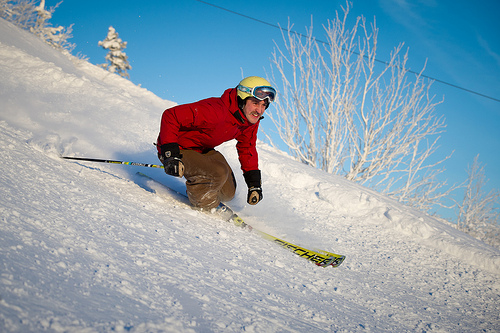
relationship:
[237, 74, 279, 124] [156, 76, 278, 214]
head of a man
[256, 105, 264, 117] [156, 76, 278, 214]
nose of a man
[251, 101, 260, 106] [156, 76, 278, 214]
eye of a man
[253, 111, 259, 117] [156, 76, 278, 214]
mouth of a man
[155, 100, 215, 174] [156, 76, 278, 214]
arm of a man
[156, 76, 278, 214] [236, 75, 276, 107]
man wearing helmet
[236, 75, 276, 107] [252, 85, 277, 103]
helmet has goggles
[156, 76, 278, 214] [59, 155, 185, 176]
man holding poles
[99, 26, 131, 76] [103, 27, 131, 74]
ice on tree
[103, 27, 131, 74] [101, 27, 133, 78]
tree in snow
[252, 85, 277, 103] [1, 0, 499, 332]
goggles for ski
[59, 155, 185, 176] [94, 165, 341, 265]
pole for ski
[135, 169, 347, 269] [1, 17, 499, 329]
skis on snow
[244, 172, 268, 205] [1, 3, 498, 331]
glove for skiing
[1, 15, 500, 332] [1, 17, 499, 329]
hillside in snow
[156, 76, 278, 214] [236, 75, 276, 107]
man wearing a helmet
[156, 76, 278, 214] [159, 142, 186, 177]
man wearing gloves